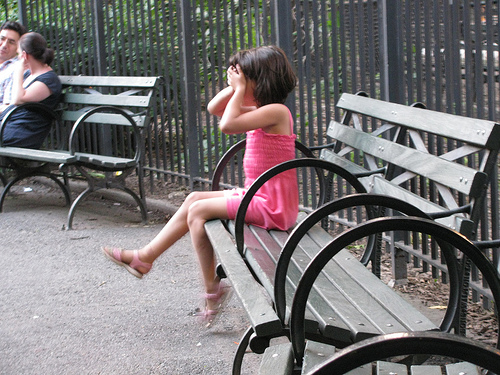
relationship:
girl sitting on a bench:
[99, 33, 305, 331] [199, 92, 494, 371]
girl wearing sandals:
[99, 33, 305, 331] [96, 232, 251, 331]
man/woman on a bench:
[0, 20, 61, 152] [85, 69, 184, 223]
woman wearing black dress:
[0, 30, 61, 157] [1, 68, 62, 152]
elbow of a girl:
[219, 117, 237, 134] [99, 33, 305, 331]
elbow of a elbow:
[219, 117, 237, 134] [203, 96, 221, 116]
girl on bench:
[99, 33, 305, 331] [177, 75, 487, 360]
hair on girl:
[227, 44, 297, 109] [99, 33, 305, 331]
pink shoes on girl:
[98, 243, 157, 279] [99, 33, 305, 331]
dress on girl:
[227, 112, 297, 230] [99, 33, 305, 331]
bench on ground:
[199, 92, 494, 371] [367, 112, 410, 172]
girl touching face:
[99, 33, 305, 331] [238, 63, 258, 107]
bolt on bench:
[450, 172, 476, 189] [193, 70, 493, 355]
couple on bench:
[0, 44, 50, 152] [24, 60, 202, 214]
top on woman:
[4, 66, 65, 150] [5, 32, 64, 155]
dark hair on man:
[222, 39, 302, 109] [1, 15, 23, 113]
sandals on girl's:
[104, 243, 156, 281] [101, 37, 309, 327]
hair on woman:
[17, 26, 56, 64] [5, 33, 72, 163]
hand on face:
[221, 64, 248, 91] [0, 29, 16, 61]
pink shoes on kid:
[113, 242, 228, 324] [196, 30, 321, 251]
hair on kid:
[227, 47, 294, 106] [93, 40, 302, 331]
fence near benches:
[21, 15, 498, 226] [1, 65, 480, 350]